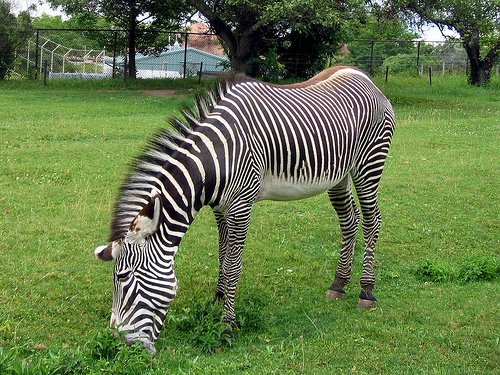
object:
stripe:
[266, 83, 320, 182]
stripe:
[119, 300, 168, 325]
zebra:
[92, 63, 397, 358]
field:
[0, 74, 499, 374]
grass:
[0, 74, 499, 375]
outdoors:
[0, 0, 499, 374]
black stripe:
[156, 174, 194, 225]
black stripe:
[182, 130, 217, 206]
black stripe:
[231, 80, 276, 175]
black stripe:
[191, 124, 225, 211]